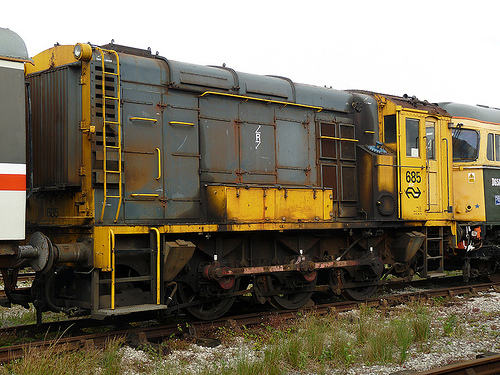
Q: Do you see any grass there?
A: Yes, there is grass.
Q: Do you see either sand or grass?
A: Yes, there is grass.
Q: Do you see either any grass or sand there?
A: Yes, there is grass.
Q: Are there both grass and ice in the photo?
A: No, there is grass but no ice.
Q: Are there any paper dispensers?
A: No, there are no paper dispensers.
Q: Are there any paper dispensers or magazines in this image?
A: No, there are no paper dispensers or magazines.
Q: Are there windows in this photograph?
A: Yes, there is a window.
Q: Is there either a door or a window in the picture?
A: Yes, there is a window.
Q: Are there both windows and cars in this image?
A: Yes, there are both a window and a car.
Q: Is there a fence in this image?
A: No, there are no fences.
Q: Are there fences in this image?
A: No, there are no fences.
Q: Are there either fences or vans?
A: No, there are no fences or vans.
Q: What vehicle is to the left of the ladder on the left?
A: The vehicle is a train car.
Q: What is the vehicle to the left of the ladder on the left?
A: The vehicle is a train car.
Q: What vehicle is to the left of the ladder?
A: The vehicle is a train car.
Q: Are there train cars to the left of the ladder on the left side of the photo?
A: Yes, there is a train car to the left of the ladder.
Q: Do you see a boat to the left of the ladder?
A: No, there is a train car to the left of the ladder.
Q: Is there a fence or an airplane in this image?
A: No, there are no fences or airplanes.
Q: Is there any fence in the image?
A: No, there are no fences.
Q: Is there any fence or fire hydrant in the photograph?
A: No, there are no fences or fire hydrants.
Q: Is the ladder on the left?
A: Yes, the ladder is on the left of the image.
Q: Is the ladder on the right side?
A: No, the ladder is on the left of the image.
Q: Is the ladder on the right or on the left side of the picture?
A: The ladder is on the left of the image.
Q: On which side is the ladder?
A: The ladder is on the left of the image.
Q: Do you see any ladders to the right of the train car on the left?
A: Yes, there is a ladder to the right of the train car.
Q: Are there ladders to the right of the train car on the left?
A: Yes, there is a ladder to the right of the train car.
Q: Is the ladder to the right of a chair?
A: No, the ladder is to the right of the train car.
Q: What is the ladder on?
A: The ladder is on the train.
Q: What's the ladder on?
A: The ladder is on the train.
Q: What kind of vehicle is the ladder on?
A: The ladder is on the train.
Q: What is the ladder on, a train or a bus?
A: The ladder is on a train.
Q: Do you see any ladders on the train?
A: Yes, there is a ladder on the train.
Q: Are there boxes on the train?
A: No, there is a ladder on the train.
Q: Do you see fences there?
A: No, there are no fences.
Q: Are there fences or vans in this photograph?
A: No, there are no fences or vans.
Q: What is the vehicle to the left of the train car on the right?
A: The vehicle is a car.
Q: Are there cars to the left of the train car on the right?
A: Yes, there is a car to the left of the train car.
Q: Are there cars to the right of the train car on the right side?
A: No, the car is to the left of the train car.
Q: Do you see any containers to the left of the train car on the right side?
A: No, there is a car to the left of the train car.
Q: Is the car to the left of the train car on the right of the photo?
A: Yes, the car is to the left of the train car.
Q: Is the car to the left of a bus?
A: No, the car is to the left of the train car.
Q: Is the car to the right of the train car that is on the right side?
A: No, the car is to the left of the train car.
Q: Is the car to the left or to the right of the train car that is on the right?
A: The car is to the left of the train car.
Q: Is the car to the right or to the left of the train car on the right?
A: The car is to the left of the train car.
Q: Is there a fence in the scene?
A: No, there are no fences.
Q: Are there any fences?
A: No, there are no fences.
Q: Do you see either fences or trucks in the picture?
A: No, there are no fences or trucks.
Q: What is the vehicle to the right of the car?
A: The vehicle is a train car.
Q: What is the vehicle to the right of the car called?
A: The vehicle is a train car.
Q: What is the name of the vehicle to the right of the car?
A: The vehicle is a train car.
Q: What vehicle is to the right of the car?
A: The vehicle is a train car.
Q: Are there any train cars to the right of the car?
A: Yes, there is a train car to the right of the car.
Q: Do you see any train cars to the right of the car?
A: Yes, there is a train car to the right of the car.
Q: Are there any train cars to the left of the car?
A: No, the train car is to the right of the car.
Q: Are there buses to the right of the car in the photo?
A: No, there is a train car to the right of the car.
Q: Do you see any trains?
A: Yes, there is a train.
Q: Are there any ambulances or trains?
A: Yes, there is a train.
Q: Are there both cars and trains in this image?
A: Yes, there are both a train and cars.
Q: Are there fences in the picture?
A: No, there are no fences.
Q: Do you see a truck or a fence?
A: No, there are no fences or trucks.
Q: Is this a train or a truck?
A: This is a train.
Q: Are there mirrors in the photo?
A: No, there are no mirrors.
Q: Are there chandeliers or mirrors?
A: No, there are no mirrors or chandeliers.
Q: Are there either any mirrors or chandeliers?
A: No, there are no mirrors or chandeliers.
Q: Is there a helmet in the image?
A: No, there are no helmets.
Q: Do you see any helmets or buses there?
A: No, there are no helmets or buses.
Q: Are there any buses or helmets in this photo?
A: No, there are no helmets or buses.